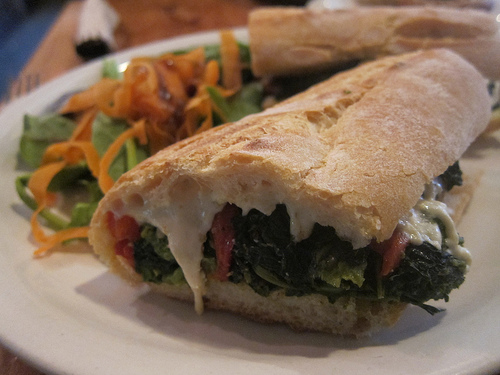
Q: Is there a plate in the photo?
A: Yes, there is a plate.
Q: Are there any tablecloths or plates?
A: Yes, there is a plate.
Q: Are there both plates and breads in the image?
A: Yes, there are both a plate and a bread.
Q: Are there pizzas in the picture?
A: No, there are no pizzas.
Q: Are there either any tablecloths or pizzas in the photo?
A: No, there are no pizzas or tablecloths.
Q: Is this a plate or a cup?
A: This is a plate.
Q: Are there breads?
A: Yes, there is a bread.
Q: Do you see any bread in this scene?
A: Yes, there is a bread.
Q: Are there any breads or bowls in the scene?
A: Yes, there is a bread.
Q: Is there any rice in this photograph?
A: No, there is no rice.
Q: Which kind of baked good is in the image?
A: The baked good is a bread.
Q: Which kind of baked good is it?
A: The food is a bread.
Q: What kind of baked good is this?
A: This is a bread.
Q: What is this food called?
A: This is a bread.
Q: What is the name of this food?
A: This is a bread.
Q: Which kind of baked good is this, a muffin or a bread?
A: This is a bread.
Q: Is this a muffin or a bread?
A: This is a bread.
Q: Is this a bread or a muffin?
A: This is a bread.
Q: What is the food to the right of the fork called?
A: The food is a bread.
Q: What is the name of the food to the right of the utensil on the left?
A: The food is a bread.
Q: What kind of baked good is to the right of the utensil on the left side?
A: The food is a bread.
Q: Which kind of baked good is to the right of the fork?
A: The food is a bread.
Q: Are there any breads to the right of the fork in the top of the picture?
A: Yes, there is a bread to the right of the fork.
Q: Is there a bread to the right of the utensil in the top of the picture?
A: Yes, there is a bread to the right of the fork.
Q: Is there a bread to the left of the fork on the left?
A: No, the bread is to the right of the fork.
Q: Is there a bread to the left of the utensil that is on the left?
A: No, the bread is to the right of the fork.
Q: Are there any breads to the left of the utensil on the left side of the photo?
A: No, the bread is to the right of the fork.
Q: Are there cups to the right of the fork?
A: No, there is a bread to the right of the fork.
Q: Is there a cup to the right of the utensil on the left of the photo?
A: No, there is a bread to the right of the fork.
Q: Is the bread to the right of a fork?
A: Yes, the bread is to the right of a fork.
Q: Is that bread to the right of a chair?
A: No, the bread is to the right of a fork.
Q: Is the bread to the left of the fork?
A: No, the bread is to the right of the fork.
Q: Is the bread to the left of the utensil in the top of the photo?
A: No, the bread is to the right of the fork.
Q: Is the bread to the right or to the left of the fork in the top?
A: The bread is to the right of the fork.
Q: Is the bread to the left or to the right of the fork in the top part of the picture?
A: The bread is to the right of the fork.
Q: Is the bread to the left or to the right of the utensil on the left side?
A: The bread is to the right of the fork.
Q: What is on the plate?
A: The bread is on the plate.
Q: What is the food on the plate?
A: The food is a bread.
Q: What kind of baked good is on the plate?
A: The food is a bread.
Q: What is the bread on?
A: The bread is on the plate.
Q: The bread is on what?
A: The bread is on the plate.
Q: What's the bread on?
A: The bread is on the plate.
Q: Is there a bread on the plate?
A: Yes, there is a bread on the plate.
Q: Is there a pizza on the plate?
A: No, there is a bread on the plate.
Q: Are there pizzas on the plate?
A: No, there is a bread on the plate.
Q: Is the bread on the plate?
A: Yes, the bread is on the plate.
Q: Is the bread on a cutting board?
A: No, the bread is on the plate.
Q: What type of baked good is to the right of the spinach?
A: The food is a bread.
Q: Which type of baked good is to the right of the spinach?
A: The food is a bread.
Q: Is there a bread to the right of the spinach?
A: Yes, there is a bread to the right of the spinach.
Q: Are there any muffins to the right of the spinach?
A: No, there is a bread to the right of the spinach.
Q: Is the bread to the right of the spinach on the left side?
A: Yes, the bread is to the right of the spinach.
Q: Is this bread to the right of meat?
A: No, the bread is to the right of the spinach.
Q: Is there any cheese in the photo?
A: Yes, there is cheese.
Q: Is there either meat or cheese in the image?
A: Yes, there is cheese.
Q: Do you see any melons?
A: No, there are no melons.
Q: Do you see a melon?
A: No, there are no melons.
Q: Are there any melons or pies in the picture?
A: No, there are no melons or pies.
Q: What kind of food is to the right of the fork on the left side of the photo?
A: The food is cheese.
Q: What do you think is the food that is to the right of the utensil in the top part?
A: The food is cheese.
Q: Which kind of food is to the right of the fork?
A: The food is cheese.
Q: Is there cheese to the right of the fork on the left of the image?
A: Yes, there is cheese to the right of the fork.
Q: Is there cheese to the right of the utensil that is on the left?
A: Yes, there is cheese to the right of the fork.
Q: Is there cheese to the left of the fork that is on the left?
A: No, the cheese is to the right of the fork.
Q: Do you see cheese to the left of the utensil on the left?
A: No, the cheese is to the right of the fork.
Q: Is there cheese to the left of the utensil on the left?
A: No, the cheese is to the right of the fork.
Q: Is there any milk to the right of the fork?
A: No, there is cheese to the right of the fork.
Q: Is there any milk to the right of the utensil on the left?
A: No, there is cheese to the right of the fork.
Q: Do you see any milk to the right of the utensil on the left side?
A: No, there is cheese to the right of the fork.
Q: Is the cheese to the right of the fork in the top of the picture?
A: Yes, the cheese is to the right of the fork.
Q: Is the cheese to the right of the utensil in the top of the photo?
A: Yes, the cheese is to the right of the fork.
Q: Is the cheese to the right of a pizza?
A: No, the cheese is to the right of the fork.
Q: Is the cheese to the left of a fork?
A: No, the cheese is to the right of a fork.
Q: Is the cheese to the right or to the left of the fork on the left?
A: The cheese is to the right of the fork.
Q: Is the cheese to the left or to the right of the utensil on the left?
A: The cheese is to the right of the fork.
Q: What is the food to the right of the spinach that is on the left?
A: The food is cheese.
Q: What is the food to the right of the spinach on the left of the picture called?
A: The food is cheese.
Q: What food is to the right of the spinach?
A: The food is cheese.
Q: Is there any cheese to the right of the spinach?
A: Yes, there is cheese to the right of the spinach.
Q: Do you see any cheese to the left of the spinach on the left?
A: No, the cheese is to the right of the spinach.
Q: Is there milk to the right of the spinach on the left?
A: No, there is cheese to the right of the spinach.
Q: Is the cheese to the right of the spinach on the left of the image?
A: Yes, the cheese is to the right of the spinach.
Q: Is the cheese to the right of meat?
A: No, the cheese is to the right of the spinach.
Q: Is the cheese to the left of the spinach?
A: No, the cheese is to the right of the spinach.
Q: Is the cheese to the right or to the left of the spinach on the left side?
A: The cheese is to the right of the spinach.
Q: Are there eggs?
A: No, there are no eggs.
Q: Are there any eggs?
A: No, there are no eggs.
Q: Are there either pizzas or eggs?
A: No, there are no eggs or pizzas.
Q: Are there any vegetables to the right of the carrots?
A: Yes, there is a vegetable to the right of the carrots.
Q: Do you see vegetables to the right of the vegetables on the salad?
A: Yes, there is a vegetable to the right of the carrots.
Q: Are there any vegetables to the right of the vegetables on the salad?
A: Yes, there is a vegetable to the right of the carrots.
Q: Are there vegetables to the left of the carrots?
A: No, the vegetable is to the right of the carrots.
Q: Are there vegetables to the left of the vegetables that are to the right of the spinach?
A: No, the vegetable is to the right of the carrots.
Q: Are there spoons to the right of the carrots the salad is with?
A: No, there is a vegetable to the right of the carrots.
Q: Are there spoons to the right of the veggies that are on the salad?
A: No, there is a vegetable to the right of the carrots.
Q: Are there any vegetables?
A: Yes, there are vegetables.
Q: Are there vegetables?
A: Yes, there are vegetables.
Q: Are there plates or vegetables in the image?
A: Yes, there are vegetables.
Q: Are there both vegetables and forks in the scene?
A: Yes, there are both vegetables and a fork.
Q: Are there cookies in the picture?
A: No, there are no cookies.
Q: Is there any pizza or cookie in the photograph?
A: No, there are no cookies or pizzas.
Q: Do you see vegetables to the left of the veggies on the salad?
A: Yes, there are vegetables to the left of the carrots.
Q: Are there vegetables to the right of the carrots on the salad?
A: No, the vegetables are to the left of the carrots.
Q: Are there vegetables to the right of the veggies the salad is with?
A: No, the vegetables are to the left of the carrots.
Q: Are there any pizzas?
A: No, there are no pizzas.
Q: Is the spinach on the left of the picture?
A: Yes, the spinach is on the left of the image.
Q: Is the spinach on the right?
A: No, the spinach is on the left of the image.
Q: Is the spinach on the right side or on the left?
A: The spinach is on the left of the image.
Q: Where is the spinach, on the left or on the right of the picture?
A: The spinach is on the left of the image.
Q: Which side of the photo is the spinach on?
A: The spinach is on the left of the image.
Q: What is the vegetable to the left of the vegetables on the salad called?
A: The vegetable is spinach.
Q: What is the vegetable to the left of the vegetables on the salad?
A: The vegetable is spinach.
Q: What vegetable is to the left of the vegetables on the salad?
A: The vegetable is spinach.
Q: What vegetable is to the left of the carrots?
A: The vegetable is spinach.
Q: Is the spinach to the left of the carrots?
A: Yes, the spinach is to the left of the carrots.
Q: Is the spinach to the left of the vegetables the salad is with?
A: Yes, the spinach is to the left of the carrots.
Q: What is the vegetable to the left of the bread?
A: The vegetable is spinach.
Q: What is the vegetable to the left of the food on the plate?
A: The vegetable is spinach.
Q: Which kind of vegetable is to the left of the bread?
A: The vegetable is spinach.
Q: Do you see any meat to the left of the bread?
A: No, there is spinach to the left of the bread.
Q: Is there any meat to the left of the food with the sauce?
A: No, there is spinach to the left of the bread.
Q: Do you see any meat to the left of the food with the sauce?
A: No, there is spinach to the left of the bread.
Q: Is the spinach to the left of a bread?
A: Yes, the spinach is to the left of a bread.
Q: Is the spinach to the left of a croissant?
A: No, the spinach is to the left of a bread.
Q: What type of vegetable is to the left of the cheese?
A: The vegetable is spinach.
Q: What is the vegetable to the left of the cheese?
A: The vegetable is spinach.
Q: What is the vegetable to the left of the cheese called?
A: The vegetable is spinach.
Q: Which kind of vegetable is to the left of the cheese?
A: The vegetable is spinach.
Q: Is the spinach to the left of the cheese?
A: Yes, the spinach is to the left of the cheese.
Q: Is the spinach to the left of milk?
A: No, the spinach is to the left of the cheese.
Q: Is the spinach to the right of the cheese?
A: No, the spinach is to the left of the cheese.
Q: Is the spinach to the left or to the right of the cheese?
A: The spinach is to the left of the cheese.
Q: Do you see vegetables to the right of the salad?
A: Yes, there is a vegetable to the right of the salad.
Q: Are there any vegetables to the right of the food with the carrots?
A: Yes, there is a vegetable to the right of the salad.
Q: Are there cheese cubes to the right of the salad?
A: No, there is a vegetable to the right of the salad.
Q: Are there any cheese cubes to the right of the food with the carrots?
A: No, there is a vegetable to the right of the salad.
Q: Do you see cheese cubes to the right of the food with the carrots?
A: No, there is a vegetable to the right of the salad.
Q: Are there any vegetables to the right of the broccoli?
A: Yes, there is a vegetable to the right of the broccoli.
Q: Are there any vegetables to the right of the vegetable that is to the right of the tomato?
A: Yes, there is a vegetable to the right of the broccoli.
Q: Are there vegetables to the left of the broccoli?
A: No, the vegetable is to the right of the broccoli.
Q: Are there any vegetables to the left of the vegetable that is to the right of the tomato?
A: No, the vegetable is to the right of the broccoli.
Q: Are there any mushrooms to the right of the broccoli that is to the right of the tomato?
A: No, there is a vegetable to the right of the broccoli.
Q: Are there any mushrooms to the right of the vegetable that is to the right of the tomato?
A: No, there is a vegetable to the right of the broccoli.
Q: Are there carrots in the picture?
A: Yes, there are carrots.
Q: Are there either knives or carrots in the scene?
A: Yes, there are carrots.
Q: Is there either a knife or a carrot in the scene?
A: Yes, there are carrots.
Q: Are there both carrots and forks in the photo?
A: Yes, there are both carrots and a fork.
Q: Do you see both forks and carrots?
A: Yes, there are both carrots and a fork.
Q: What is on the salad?
A: The carrots are on the salad.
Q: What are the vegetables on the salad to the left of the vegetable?
A: The vegetables are carrots.